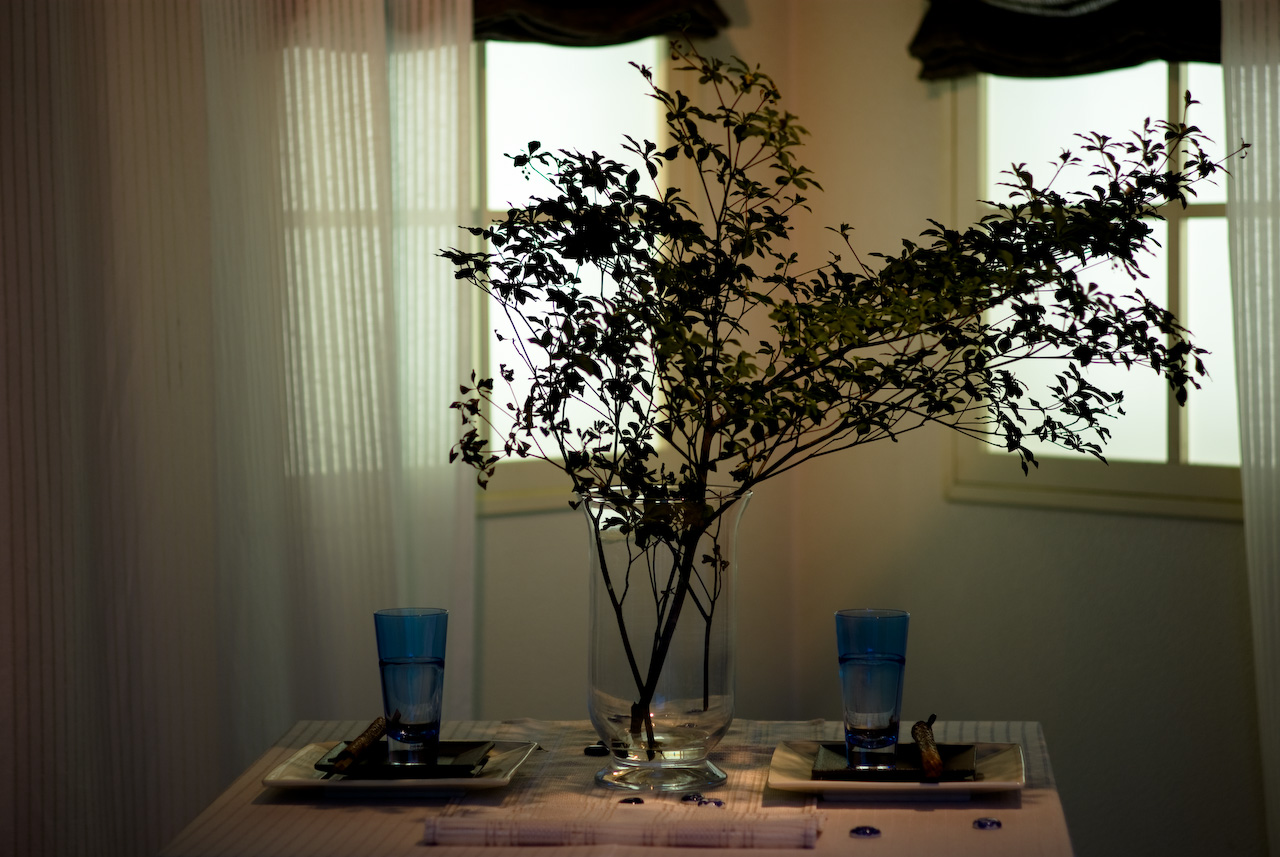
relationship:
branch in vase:
[440, 42, 1235, 758] [570, 479, 751, 791]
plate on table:
[811, 733, 979, 787] [171, 694, 1115, 854]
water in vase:
[596, 524, 725, 758] [570, 479, 751, 791]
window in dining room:
[281, 11, 659, 464] [7, 9, 1276, 848]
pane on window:
[281, 18, 474, 213] [281, 11, 659, 464]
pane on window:
[266, 221, 483, 480] [281, 11, 659, 464]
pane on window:
[491, 230, 673, 454] [279, 40, 677, 460]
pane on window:
[482, 34, 674, 224] [277, 5, 688, 476]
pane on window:
[947, 27, 1179, 211] [928, 3, 1184, 205]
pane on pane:
[1175, 36, 1277, 220] [979, 61, 1279, 467]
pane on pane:
[983, 210, 1171, 466] [979, 61, 1279, 467]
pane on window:
[1181, 204, 1257, 481] [963, 69, 1268, 476]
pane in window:
[802, 589, 919, 742] [271, 26, 699, 498]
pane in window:
[935, 11, 1242, 517] [941, 40, 1276, 505]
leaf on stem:
[550, 443, 612, 480] [463, 54, 1215, 604]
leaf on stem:
[592, 508, 643, 549] [592, 480, 699, 759]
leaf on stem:
[627, 478, 661, 536] [594, 459, 717, 766]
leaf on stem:
[741, 389, 773, 442] [585, 389, 775, 759]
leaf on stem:
[567, 449, 599, 490] [527, 504, 765, 750]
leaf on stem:
[630, 442, 648, 486] [575, 452, 821, 725]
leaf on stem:
[560, 190, 604, 252] [252, 38, 733, 469]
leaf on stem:
[1032, 186, 1071, 211] [950, 44, 1225, 498]